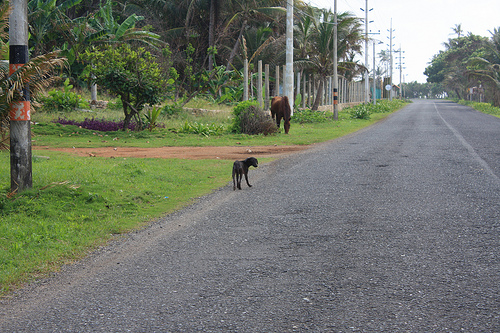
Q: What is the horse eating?
A: Grass.